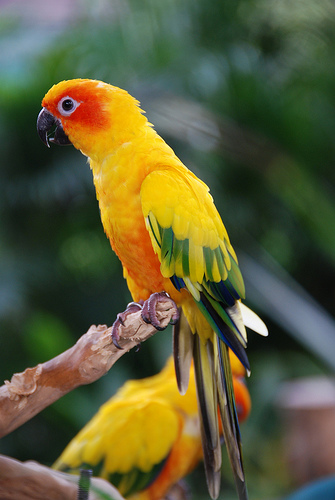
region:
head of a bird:
[34, 72, 136, 131]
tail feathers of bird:
[170, 295, 293, 452]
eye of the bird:
[52, 87, 90, 117]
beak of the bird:
[26, 102, 71, 144]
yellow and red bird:
[23, 66, 150, 169]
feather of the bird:
[125, 150, 226, 280]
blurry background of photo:
[196, 30, 306, 109]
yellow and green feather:
[136, 176, 229, 276]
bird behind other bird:
[53, 326, 271, 493]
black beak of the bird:
[24, 104, 67, 159]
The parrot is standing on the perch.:
[21, 36, 250, 373]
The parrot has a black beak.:
[23, 94, 69, 149]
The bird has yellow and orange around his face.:
[40, 80, 120, 135]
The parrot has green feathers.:
[159, 219, 183, 279]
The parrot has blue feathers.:
[209, 275, 239, 305]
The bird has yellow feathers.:
[142, 171, 187, 228]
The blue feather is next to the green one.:
[194, 295, 243, 338]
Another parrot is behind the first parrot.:
[35, 74, 266, 487]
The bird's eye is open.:
[47, 87, 84, 114]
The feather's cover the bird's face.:
[176, 307, 259, 463]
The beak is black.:
[28, 108, 70, 151]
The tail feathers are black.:
[170, 305, 260, 497]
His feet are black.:
[100, 294, 180, 348]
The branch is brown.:
[2, 288, 191, 431]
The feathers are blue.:
[191, 292, 263, 365]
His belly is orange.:
[103, 211, 161, 305]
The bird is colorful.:
[40, 65, 306, 497]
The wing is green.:
[153, 226, 246, 292]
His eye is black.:
[57, 93, 81, 116]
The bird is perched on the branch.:
[24, 56, 260, 357]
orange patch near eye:
[47, 103, 104, 132]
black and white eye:
[38, 96, 83, 128]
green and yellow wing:
[126, 171, 229, 271]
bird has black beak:
[29, 100, 62, 143]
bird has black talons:
[91, 232, 192, 364]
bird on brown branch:
[12, 286, 186, 440]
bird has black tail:
[152, 302, 262, 480]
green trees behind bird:
[106, 13, 321, 249]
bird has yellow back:
[127, 107, 184, 175]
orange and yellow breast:
[96, 197, 167, 280]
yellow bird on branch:
[65, 337, 269, 498]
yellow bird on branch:
[26, 64, 282, 380]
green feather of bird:
[161, 228, 181, 264]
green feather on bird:
[219, 249, 253, 305]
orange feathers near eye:
[44, 85, 117, 138]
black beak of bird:
[31, 105, 72, 154]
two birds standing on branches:
[23, 70, 266, 498]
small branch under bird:
[4, 288, 177, 445]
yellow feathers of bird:
[122, 132, 186, 195]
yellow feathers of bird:
[100, 398, 145, 450]